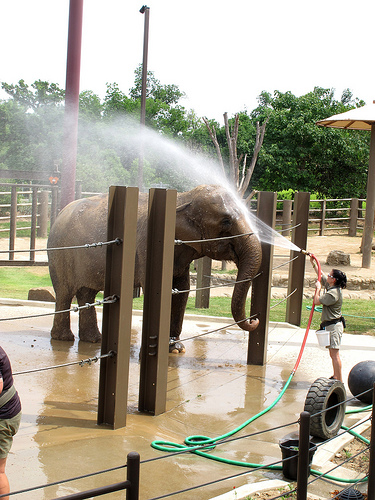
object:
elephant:
[45, 183, 263, 356]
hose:
[217, 373, 289, 439]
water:
[67, 115, 301, 294]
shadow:
[39, 388, 95, 430]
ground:
[170, 373, 268, 439]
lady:
[312, 258, 347, 382]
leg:
[331, 348, 342, 376]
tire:
[302, 378, 346, 439]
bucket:
[279, 436, 317, 481]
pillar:
[135, 185, 192, 414]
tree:
[273, 103, 336, 184]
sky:
[195, 4, 291, 92]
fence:
[271, 200, 326, 250]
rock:
[328, 249, 352, 264]